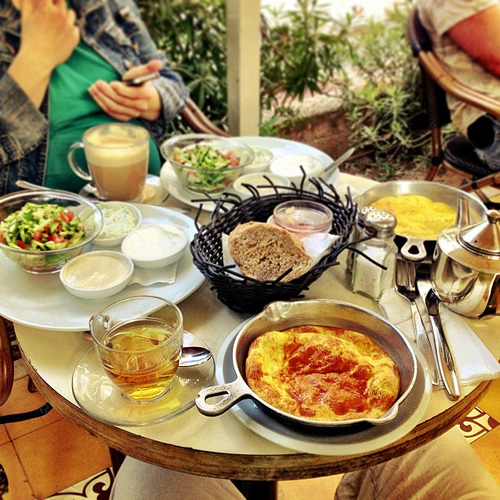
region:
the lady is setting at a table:
[6, 2, 498, 494]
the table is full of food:
[18, 127, 499, 470]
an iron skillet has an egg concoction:
[198, 295, 416, 434]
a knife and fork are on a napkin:
[393, 255, 490, 397]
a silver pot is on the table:
[435, 192, 499, 323]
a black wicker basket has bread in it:
[177, 172, 363, 305]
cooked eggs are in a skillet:
[355, 171, 484, 273]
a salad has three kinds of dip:
[0, 185, 185, 299]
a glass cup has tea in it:
[91, 298, 183, 395]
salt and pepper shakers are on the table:
[346, 205, 396, 298]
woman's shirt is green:
[36, 39, 163, 187]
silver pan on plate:
[224, 287, 456, 454]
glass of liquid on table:
[82, 288, 179, 405]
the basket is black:
[166, 136, 391, 318]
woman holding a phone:
[97, 48, 196, 128]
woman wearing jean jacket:
[1, 3, 196, 165]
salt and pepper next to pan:
[350, 193, 398, 313]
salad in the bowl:
[3, 183, 112, 284]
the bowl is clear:
[1, 168, 122, 291]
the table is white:
[18, 151, 495, 497]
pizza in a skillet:
[195, 297, 417, 439]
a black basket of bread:
[190, 165, 368, 315]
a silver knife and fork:
[395, 255, 467, 401]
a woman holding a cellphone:
[0, 2, 186, 179]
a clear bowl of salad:
[2, 187, 98, 275]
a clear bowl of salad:
[163, 129, 250, 191]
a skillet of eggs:
[355, 174, 484, 284]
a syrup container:
[424, 194, 499, 319]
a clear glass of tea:
[66, 292, 213, 429]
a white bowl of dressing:
[56, 243, 133, 299]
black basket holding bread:
[189, 196, 366, 306]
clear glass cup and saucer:
[64, 293, 213, 430]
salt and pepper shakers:
[350, 193, 407, 310]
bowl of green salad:
[7, 191, 107, 269]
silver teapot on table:
[432, 183, 499, 347]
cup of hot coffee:
[62, 118, 161, 208]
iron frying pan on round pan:
[205, 288, 429, 443]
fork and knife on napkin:
[392, 251, 462, 407]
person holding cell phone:
[83, 41, 187, 125]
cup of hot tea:
[93, 303, 188, 401]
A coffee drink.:
[61, 122, 156, 202]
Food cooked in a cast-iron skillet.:
[200, 295, 420, 435]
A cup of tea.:
[80, 300, 190, 401]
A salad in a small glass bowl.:
[0, 175, 110, 272]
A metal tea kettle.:
[430, 195, 496, 320]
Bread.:
[230, 215, 310, 281]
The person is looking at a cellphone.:
[0, 0, 200, 126]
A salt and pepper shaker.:
[335, 200, 410, 302]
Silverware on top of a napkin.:
[395, 255, 475, 415]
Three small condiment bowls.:
[62, 201, 192, 293]